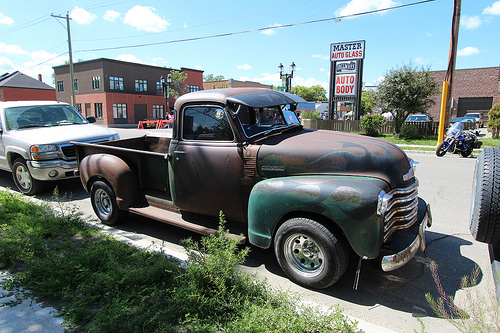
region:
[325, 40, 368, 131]
auto glass body shop sign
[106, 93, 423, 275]
rusted antique Chevrolet truck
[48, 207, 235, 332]
green weeds and grass on curb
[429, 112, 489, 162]
motorcycle beside yellow pole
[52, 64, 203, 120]
red and brown multi-story building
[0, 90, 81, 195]
late model white pickup truck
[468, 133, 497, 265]
spare tire on back of vehicle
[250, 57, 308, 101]
double light lamppost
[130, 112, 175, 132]
red street blocking sign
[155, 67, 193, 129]
green tree next to warning sign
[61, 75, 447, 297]
vehicle parked on a street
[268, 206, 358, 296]
front wheel on a vehicle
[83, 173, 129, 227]
rear wheel on a vehicle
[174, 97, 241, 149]
side window on a vehicle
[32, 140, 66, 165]
front headlight on a vehicle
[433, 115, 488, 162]
motorcycle on a street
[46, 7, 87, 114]
utility pole near a street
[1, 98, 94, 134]
front windshield on a vehicle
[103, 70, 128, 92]
windows on a building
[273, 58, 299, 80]
streetlights on a pole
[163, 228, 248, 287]
green bushes in the enclosure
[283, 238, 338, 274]
silver spokes in the wheel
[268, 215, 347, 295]
grooved black tires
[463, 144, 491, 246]
tire in front of the truck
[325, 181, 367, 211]
rust on the side of the truck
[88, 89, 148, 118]
red paint on the building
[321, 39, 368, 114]
large sign on the sidewalk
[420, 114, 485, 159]
bike parked on side of road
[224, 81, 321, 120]
visor on front of truck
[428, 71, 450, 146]
yellow post on side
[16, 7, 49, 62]
white clouds in blue sky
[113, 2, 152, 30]
white clouds in blue sky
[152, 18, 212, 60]
white clouds in blue sky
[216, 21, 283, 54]
white clouds in blue sky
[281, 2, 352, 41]
white clouds in blue sky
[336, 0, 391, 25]
white clouds in blue sky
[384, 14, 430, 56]
white clouds in blue sky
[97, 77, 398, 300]
old truck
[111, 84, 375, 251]
old stained truck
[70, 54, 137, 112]
brown and red building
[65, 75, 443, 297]
An old truck parked on the street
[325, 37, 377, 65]
An auto glass sign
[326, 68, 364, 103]
an auto body sign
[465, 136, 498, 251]
A spare tire on the back of a vehicle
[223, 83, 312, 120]
A window visor on an old truck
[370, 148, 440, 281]
A chrome grill and bumper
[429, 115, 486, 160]
a motorcycle parked in the street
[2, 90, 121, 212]
A silver truck parked by the curb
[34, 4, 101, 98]
A telephone pole across the street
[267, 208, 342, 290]
A chrome wheel on an old truck